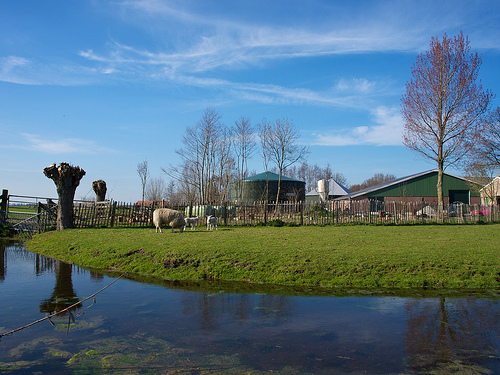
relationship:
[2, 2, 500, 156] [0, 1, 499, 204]
clouds in sky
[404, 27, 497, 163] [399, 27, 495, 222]
leaves on tree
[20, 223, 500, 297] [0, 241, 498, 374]
grass near pond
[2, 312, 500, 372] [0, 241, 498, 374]
moss under pond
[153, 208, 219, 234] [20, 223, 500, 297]
animals on grass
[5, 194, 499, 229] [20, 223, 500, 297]
fence behind grass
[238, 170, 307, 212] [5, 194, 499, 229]
silo behind fence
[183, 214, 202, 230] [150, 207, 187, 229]
lamb near sheep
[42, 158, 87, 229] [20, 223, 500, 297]
cut-off tree on grass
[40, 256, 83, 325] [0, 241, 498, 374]
reflection on pond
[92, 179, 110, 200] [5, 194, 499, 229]
tree behind fence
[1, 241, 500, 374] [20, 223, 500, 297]
water near grass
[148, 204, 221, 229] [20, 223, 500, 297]
animals on grass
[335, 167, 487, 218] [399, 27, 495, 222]
building behind tree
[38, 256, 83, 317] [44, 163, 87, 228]
reflection of tree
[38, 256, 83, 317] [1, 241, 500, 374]
reflection in water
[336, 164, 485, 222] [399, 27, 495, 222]
house behind tree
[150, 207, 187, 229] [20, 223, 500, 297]
sheep on grass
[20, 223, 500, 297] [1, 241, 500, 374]
grass next to water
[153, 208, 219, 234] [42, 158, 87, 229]
animals standing near cut-off tree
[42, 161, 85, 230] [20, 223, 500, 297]
tree trunk on grass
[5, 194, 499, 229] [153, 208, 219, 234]
fence behind animals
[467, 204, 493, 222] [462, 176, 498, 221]
car by barn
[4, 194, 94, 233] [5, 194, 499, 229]
gate behind fence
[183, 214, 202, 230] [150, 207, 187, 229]
lamb standing by sheep